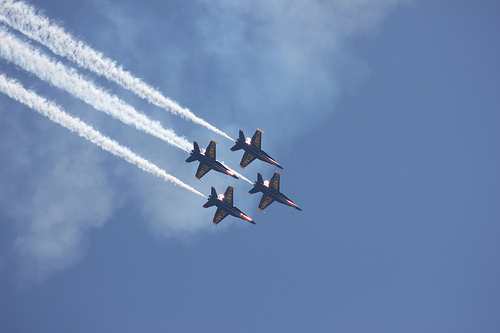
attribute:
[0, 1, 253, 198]
smoke — white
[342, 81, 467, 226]
sky — blue, clear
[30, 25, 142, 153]
clouds — white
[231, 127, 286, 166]
jet — with smoke tracks, figher's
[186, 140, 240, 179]
jet — figher's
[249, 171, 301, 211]
jet — figher's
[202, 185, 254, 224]
jet — figher's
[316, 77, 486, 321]
sky — blue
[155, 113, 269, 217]
jets — white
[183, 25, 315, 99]
clouds — white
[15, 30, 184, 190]
trails — smoke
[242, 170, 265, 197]
tail — airplane's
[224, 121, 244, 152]
tail — airplane's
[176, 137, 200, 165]
tail — airplane's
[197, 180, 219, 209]
tail — airplane's